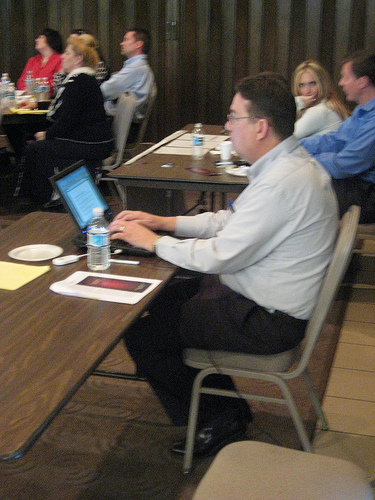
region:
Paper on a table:
[45, 259, 170, 335]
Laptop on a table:
[35, 158, 179, 268]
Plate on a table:
[6, 233, 83, 286]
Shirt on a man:
[193, 151, 333, 319]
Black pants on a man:
[139, 278, 287, 466]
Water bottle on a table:
[184, 119, 217, 162]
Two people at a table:
[267, 35, 369, 118]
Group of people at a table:
[16, 24, 154, 159]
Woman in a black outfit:
[36, 42, 114, 156]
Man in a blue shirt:
[97, 28, 170, 134]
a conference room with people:
[10, 5, 370, 486]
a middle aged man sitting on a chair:
[61, 72, 347, 437]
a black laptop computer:
[59, 152, 180, 265]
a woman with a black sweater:
[17, 33, 109, 203]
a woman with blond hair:
[283, 53, 345, 137]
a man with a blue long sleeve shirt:
[300, 54, 373, 228]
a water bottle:
[85, 204, 113, 277]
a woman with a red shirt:
[13, 27, 70, 99]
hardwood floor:
[23, 361, 160, 497]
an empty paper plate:
[7, 234, 68, 267]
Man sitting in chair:
[165, 87, 348, 455]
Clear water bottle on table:
[75, 205, 122, 276]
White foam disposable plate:
[5, 238, 70, 263]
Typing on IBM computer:
[52, 158, 175, 256]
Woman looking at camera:
[282, 54, 329, 116]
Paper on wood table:
[55, 261, 156, 325]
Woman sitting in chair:
[38, 34, 126, 171]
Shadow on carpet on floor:
[92, 400, 161, 490]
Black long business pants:
[116, 277, 287, 457]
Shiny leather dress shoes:
[152, 412, 252, 465]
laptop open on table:
[42, 137, 181, 276]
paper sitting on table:
[41, 256, 173, 310]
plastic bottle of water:
[72, 201, 125, 279]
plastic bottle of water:
[176, 116, 216, 170]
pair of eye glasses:
[209, 94, 285, 149]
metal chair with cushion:
[156, 184, 370, 490]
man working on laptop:
[113, 58, 357, 474]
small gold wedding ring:
[110, 222, 131, 237]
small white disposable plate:
[3, 228, 73, 266]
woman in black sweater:
[0, 30, 120, 213]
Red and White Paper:
[59, 268, 159, 308]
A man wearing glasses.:
[204, 72, 347, 417]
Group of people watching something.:
[25, 30, 174, 166]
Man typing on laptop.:
[63, 61, 369, 461]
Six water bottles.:
[1, 65, 61, 118]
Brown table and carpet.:
[3, 344, 147, 498]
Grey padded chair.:
[161, 210, 364, 460]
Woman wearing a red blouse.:
[12, 28, 76, 105]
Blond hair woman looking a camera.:
[282, 40, 359, 138]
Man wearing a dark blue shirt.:
[298, 53, 371, 213]